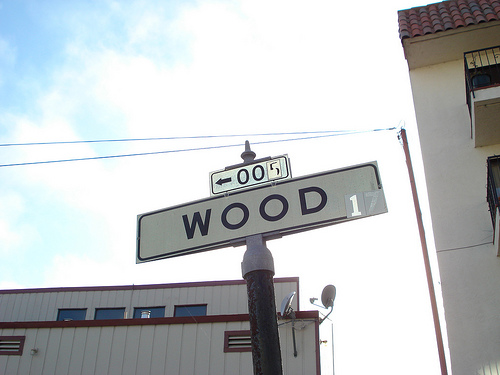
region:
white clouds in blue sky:
[31, 32, 136, 109]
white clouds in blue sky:
[34, 72, 79, 116]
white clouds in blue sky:
[14, 183, 85, 237]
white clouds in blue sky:
[248, 25, 292, 52]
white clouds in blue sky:
[315, 23, 349, 58]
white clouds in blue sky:
[375, 285, 432, 337]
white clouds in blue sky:
[111, 38, 166, 72]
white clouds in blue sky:
[152, 39, 207, 96]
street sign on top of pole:
[134, 147, 391, 373]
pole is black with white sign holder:
[238, 236, 288, 373]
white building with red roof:
[400, 2, 494, 373]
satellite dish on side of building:
[304, 278, 340, 325]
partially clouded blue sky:
[1, 4, 399, 144]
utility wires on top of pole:
[0, 121, 408, 166]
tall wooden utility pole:
[398, 127, 454, 374]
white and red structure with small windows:
[3, 282, 246, 374]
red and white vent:
[0, 332, 26, 355]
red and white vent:
[220, 327, 253, 354]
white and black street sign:
[120, 145, 390, 370]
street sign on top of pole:
[120, 145, 405, 280]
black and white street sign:
[101, 145, 396, 280]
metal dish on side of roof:
[276, 280, 313, 364]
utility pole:
[391, 113, 471, 374]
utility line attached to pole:
[0, 92, 412, 163]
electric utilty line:
[8, 113, 471, 157]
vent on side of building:
[218, 328, 263, 354]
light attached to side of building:
[26, 346, 51, 358]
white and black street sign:
[102, 129, 389, 259]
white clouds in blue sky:
[8, 103, 50, 138]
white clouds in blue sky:
[12, 186, 80, 256]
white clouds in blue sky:
[101, 71, 152, 115]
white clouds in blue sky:
[182, 43, 254, 97]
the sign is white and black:
[128, 157, 389, 273]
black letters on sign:
[168, 183, 339, 242]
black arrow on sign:
[208, 172, 235, 190]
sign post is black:
[244, 271, 299, 373]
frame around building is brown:
[1, 282, 329, 374]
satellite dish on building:
[316, 277, 346, 332]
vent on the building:
[218, 329, 253, 356]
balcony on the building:
[455, 43, 498, 148]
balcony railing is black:
[450, 42, 497, 138]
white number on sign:
[342, 191, 366, 220]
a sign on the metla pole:
[159, 138, 368, 374]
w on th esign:
[180, 198, 208, 235]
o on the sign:
[228, 192, 245, 242]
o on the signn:
[263, 191, 289, 221]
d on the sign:
[294, 175, 316, 212]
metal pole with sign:
[160, 155, 330, 367]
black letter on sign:
[178, 206, 210, 241]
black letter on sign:
[216, 195, 248, 236]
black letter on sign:
[257, 193, 289, 220]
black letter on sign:
[298, 182, 324, 217]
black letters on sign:
[173, 178, 332, 236]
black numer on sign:
[237, 165, 247, 187]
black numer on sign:
[268, 158, 280, 179]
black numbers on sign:
[237, 160, 282, 185]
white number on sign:
[348, 194, 358, 221]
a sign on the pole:
[160, 154, 380, 265]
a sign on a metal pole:
[187, 161, 312, 316]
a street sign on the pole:
[212, 180, 324, 332]